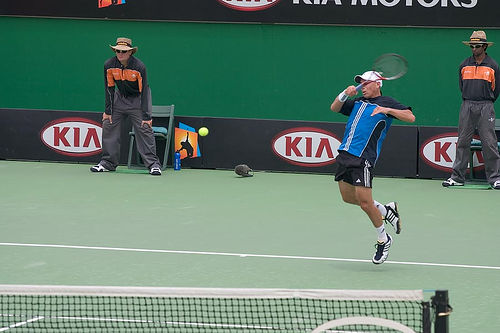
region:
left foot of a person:
[369, 236, 397, 268]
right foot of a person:
[383, 196, 406, 238]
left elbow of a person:
[396, 106, 424, 132]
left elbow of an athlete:
[399, 102, 420, 132]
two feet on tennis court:
[346, 192, 424, 266]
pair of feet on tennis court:
[365, 193, 417, 273]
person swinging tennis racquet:
[302, 19, 411, 245]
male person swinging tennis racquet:
[303, 42, 431, 268]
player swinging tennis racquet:
[315, 45, 424, 282]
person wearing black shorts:
[314, 146, 396, 213]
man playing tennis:
[336, 56, 421, 265]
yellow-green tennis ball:
[181, 119, 234, 152]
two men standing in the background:
[63, 27, 498, 177]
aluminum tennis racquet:
[344, 42, 414, 103]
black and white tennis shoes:
[366, 195, 419, 266]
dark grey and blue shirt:
[340, 85, 405, 172]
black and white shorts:
[334, 154, 381, 188]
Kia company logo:
[267, 132, 346, 165]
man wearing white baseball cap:
[349, 69, 403, 95]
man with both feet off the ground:
[327, 48, 409, 275]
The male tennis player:
[317, 50, 428, 266]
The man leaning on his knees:
[72, 31, 176, 176]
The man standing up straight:
[442, 20, 499, 188]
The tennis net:
[1, 280, 456, 331]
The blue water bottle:
[168, 143, 185, 173]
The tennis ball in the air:
[194, 119, 215, 143]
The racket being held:
[358, 50, 412, 90]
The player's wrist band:
[336, 88, 350, 104]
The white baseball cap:
[353, 64, 386, 86]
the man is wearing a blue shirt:
[331, 80, 413, 162]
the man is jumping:
[328, 52, 413, 264]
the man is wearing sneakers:
[373, 202, 398, 265]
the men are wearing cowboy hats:
[110, 29, 493, 54]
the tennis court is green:
[0, 161, 498, 330]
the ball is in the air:
[199, 127, 207, 136]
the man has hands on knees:
[101, 112, 155, 130]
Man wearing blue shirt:
[329, 54, 415, 265]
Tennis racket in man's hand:
[349, 51, 411, 94]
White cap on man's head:
[353, 68, 387, 85]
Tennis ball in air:
[186, 117, 212, 144]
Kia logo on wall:
[256, 124, 348, 171]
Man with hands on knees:
[85, 38, 162, 179]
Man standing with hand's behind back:
[443, 30, 498, 190]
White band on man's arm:
[333, 86, 348, 107]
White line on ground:
[0, 238, 498, 280]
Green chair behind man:
[125, 98, 178, 174]